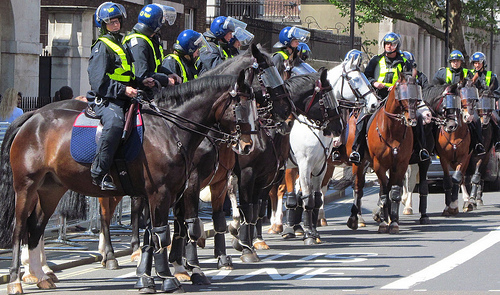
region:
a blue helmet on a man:
[92, 0, 124, 32]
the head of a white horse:
[329, 60, 380, 120]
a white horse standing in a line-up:
[287, 45, 380, 245]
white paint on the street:
[204, 248, 377, 285]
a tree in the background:
[330, 3, 498, 55]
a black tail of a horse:
[0, 109, 38, 250]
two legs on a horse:
[2, 168, 65, 293]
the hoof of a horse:
[36, 273, 58, 294]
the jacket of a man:
[361, 51, 407, 96]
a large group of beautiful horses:
[13, 47, 443, 292]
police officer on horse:
[89, 3, 131, 186]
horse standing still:
[1, 69, 249, 289]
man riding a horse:
[368, 31, 420, 245]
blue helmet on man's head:
[92, 3, 126, 23]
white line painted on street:
[379, 228, 499, 293]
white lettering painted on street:
[207, 243, 367, 285]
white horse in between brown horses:
[280, 51, 381, 235]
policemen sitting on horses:
[2, 9, 494, 291]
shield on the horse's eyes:
[397, 84, 424, 101]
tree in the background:
[337, 0, 497, 49]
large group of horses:
[5, 34, 495, 284]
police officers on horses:
[9, 8, 495, 294]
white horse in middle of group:
[305, 50, 377, 243]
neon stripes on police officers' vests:
[96, 30, 492, 110]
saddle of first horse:
[66, 89, 145, 174]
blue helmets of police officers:
[95, 5, 492, 71]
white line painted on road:
[383, 214, 498, 294]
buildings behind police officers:
[4, 7, 498, 106]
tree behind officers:
[387, 2, 479, 74]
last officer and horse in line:
[467, 57, 494, 216]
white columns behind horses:
[2, 0, 97, 121]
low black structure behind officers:
[255, 17, 365, 57]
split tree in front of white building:
[375, 5, 492, 65]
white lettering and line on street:
[190, 230, 491, 280]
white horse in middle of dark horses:
[91, 36, 491, 198]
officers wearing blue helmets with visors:
[86, 5, 491, 65]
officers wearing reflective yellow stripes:
[86, 30, 491, 100]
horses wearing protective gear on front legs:
[130, 175, 485, 280]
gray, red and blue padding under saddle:
[66, 95, 143, 165]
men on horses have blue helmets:
[80, 2, 290, 72]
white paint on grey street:
[205, 191, 495, 281]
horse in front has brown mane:
[134, 65, 249, 106]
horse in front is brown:
[21, 107, 206, 266]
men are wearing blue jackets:
[82, 47, 400, 86]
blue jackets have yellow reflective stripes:
[67, 30, 437, 150]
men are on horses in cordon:
[52, 53, 495, 235]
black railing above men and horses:
[229, 1, 304, 23]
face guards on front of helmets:
[218, 15, 338, 57]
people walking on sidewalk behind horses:
[19, 77, 84, 105]